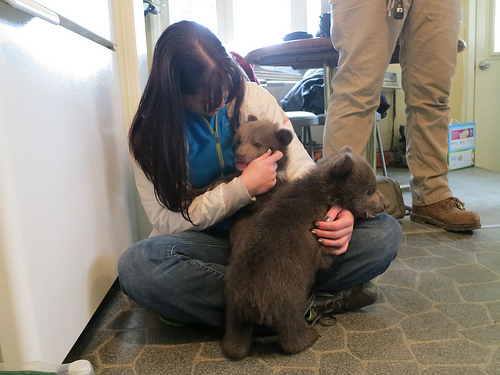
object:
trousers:
[323, 0, 463, 209]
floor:
[63, 166, 500, 374]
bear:
[217, 143, 391, 360]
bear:
[208, 115, 294, 248]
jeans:
[117, 205, 405, 332]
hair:
[127, 20, 248, 227]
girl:
[116, 19, 405, 335]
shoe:
[308, 281, 378, 325]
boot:
[410, 197, 482, 233]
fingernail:
[311, 229, 319, 238]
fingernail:
[324, 215, 331, 224]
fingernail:
[314, 221, 320, 228]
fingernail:
[318, 239, 324, 246]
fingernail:
[331, 251, 335, 257]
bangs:
[201, 60, 246, 113]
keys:
[389, 0, 402, 17]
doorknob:
[477, 59, 490, 72]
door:
[461, 0, 499, 173]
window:
[489, 1, 500, 57]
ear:
[331, 153, 356, 178]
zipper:
[209, 124, 221, 147]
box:
[446, 117, 477, 173]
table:
[243, 33, 465, 71]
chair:
[231, 49, 319, 163]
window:
[168, 0, 322, 53]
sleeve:
[128, 150, 250, 236]